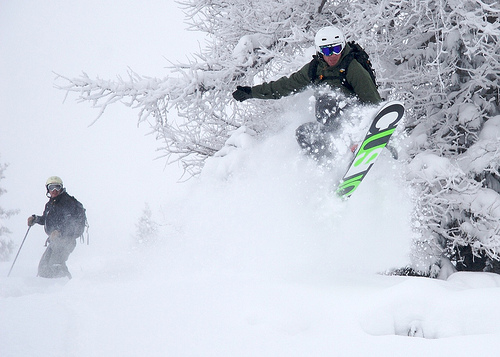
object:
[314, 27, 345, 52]
helmet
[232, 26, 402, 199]
man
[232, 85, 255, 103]
gloves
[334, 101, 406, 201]
board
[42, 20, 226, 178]
snow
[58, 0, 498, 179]
tree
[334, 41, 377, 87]
backpack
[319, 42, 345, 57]
goggles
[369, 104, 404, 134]
letters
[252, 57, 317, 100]
arm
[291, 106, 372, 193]
snow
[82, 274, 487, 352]
ground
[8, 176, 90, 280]
man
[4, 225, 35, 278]
poles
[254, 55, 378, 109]
jacket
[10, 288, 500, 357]
snow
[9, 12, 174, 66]
sky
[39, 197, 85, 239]
coat